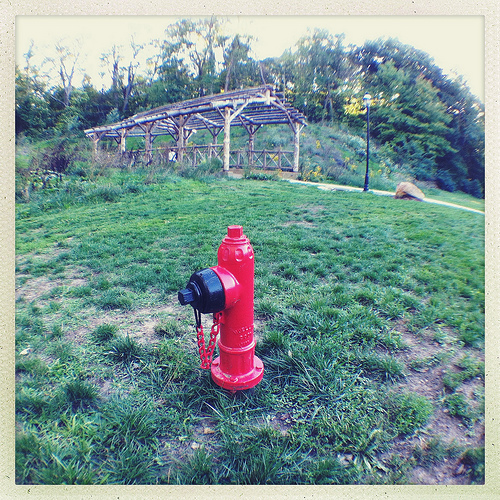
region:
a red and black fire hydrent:
[175, 223, 278, 394]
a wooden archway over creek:
[72, 85, 313, 200]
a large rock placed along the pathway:
[392, 178, 429, 205]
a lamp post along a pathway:
[358, 88, 375, 195]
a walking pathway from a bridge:
[230, 160, 480, 232]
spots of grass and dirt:
[34, 252, 156, 405]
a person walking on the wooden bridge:
[160, 142, 180, 167]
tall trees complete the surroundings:
[296, 23, 478, 212]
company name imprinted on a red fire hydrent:
[229, 323, 257, 345]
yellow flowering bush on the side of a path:
[304, 160, 330, 183]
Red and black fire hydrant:
[179, 224, 277, 403]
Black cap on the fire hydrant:
[175, 267, 224, 317]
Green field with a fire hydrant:
[34, 192, 442, 462]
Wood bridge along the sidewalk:
[88, 78, 313, 185]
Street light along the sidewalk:
[355, 86, 378, 196]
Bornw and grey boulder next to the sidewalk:
[391, 174, 426, 206]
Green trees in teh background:
[281, 28, 466, 190]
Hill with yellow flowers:
[304, 125, 371, 182]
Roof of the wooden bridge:
[87, 83, 303, 131]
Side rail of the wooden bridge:
[229, 148, 299, 170]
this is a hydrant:
[171, 195, 276, 408]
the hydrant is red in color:
[228, 277, 260, 333]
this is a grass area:
[324, 308, 418, 440]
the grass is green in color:
[318, 372, 344, 412]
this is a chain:
[184, 319, 231, 359]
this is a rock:
[401, 180, 421, 192]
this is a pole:
[355, 86, 376, 206]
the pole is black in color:
[352, 107, 382, 174]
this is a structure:
[160, 93, 233, 140]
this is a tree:
[395, 65, 450, 158]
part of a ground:
[336, 218, 385, 273]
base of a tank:
[231, 366, 269, 396]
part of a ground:
[415, 343, 475, 410]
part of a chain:
[188, 317, 236, 366]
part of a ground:
[392, 392, 423, 455]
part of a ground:
[408, 394, 430, 437]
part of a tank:
[233, 310, 257, 334]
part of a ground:
[436, 395, 461, 430]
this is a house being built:
[115, 87, 306, 170]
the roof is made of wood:
[210, 82, 272, 119]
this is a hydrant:
[183, 222, 267, 398]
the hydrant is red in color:
[220, 233, 259, 381]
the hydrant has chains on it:
[191, 320, 221, 365]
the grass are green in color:
[290, 266, 390, 385]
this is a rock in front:
[386, 177, 423, 199]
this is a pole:
[355, 90, 374, 188]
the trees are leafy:
[366, 50, 428, 107]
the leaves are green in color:
[393, 81, 429, 129]